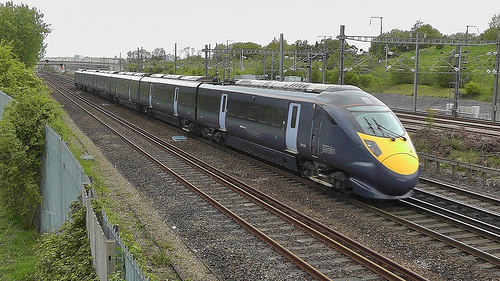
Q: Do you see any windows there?
A: Yes, there is a window.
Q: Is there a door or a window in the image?
A: Yes, there is a window.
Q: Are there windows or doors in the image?
A: Yes, there is a window.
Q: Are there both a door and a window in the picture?
A: Yes, there are both a window and a door.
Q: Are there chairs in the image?
A: No, there are no chairs.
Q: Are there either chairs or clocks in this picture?
A: No, there are no chairs or clocks.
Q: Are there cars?
A: No, there are no cars.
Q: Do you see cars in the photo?
A: No, there are no cars.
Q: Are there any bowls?
A: No, there are no bowls.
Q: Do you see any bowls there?
A: No, there are no bowls.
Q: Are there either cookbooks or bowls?
A: No, there are no bowls or cookbooks.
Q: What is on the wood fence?
A: The shrub is on the fence.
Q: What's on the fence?
A: The shrub is on the fence.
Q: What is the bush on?
A: The bush is on the fence.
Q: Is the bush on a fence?
A: Yes, the bush is on a fence.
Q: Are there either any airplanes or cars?
A: No, there are no cars or airplanes.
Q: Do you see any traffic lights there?
A: No, there are no traffic lights.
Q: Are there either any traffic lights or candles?
A: No, there are no traffic lights or candles.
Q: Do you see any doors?
A: Yes, there is a door.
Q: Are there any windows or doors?
A: Yes, there is a door.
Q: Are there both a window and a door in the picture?
A: Yes, there are both a door and a window.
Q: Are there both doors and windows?
A: Yes, there are both a door and a window.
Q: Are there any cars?
A: No, there are no cars.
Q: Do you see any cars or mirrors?
A: No, there are no cars or mirrors.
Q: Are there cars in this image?
A: No, there are no cars.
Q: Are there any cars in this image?
A: No, there are no cars.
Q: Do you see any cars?
A: No, there are no cars.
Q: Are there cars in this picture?
A: No, there are no cars.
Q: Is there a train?
A: Yes, there is a train.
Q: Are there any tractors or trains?
A: Yes, there is a train.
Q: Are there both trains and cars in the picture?
A: No, there is a train but no cars.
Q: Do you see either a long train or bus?
A: Yes, there is a long train.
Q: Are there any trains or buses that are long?
A: Yes, the train is long.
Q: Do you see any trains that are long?
A: Yes, there is a long train.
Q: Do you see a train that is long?
A: Yes, there is a train that is long.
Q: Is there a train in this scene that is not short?
A: Yes, there is a long train.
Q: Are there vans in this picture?
A: No, there are no vans.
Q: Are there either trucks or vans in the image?
A: No, there are no vans or trucks.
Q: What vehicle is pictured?
A: The vehicle is a train.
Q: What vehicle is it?
A: The vehicle is a train.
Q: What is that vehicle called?
A: This is a train.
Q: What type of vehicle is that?
A: This is a train.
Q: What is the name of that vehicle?
A: This is a train.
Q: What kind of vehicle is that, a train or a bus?
A: This is a train.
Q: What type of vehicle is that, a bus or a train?
A: This is a train.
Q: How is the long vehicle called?
A: The vehicle is a train.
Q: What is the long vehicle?
A: The vehicle is a train.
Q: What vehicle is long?
A: The vehicle is a train.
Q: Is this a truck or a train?
A: This is a train.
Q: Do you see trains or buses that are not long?
A: No, there is a train but it is long.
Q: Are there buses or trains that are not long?
A: No, there is a train but it is long.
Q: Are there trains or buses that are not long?
A: No, there is a train but it is long.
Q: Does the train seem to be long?
A: Yes, the train is long.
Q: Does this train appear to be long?
A: Yes, the train is long.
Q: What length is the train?
A: The train is long.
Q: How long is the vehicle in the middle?
A: The train is long.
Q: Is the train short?
A: No, the train is long.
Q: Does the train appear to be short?
A: No, the train is long.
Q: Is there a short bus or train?
A: No, there is a train but it is long.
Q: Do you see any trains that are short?
A: No, there is a train but it is long.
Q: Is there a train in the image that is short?
A: No, there is a train but it is long.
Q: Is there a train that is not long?
A: No, there is a train but it is long.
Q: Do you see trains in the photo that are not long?
A: No, there is a train but it is long.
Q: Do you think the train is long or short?
A: The train is long.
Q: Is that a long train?
A: Yes, that is a long train.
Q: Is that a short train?
A: No, that is a long train.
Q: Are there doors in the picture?
A: Yes, there is a door.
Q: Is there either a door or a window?
A: Yes, there is a door.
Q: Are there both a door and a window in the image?
A: Yes, there are both a door and a window.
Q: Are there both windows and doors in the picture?
A: Yes, there are both a door and a window.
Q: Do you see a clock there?
A: No, there are no clocks.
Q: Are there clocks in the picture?
A: No, there are no clocks.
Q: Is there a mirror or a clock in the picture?
A: No, there are no clocks or mirrors.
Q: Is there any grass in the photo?
A: Yes, there is grass.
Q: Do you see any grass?
A: Yes, there is grass.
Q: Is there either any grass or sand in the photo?
A: Yes, there is grass.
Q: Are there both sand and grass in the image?
A: No, there is grass but no sand.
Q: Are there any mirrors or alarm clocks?
A: No, there are no mirrors or alarm clocks.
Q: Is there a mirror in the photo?
A: No, there are no mirrors.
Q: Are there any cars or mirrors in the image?
A: No, there are no mirrors or cars.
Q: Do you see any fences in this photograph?
A: Yes, there is a fence.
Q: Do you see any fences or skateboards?
A: Yes, there is a fence.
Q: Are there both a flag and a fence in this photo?
A: No, there is a fence but no flags.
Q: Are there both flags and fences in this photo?
A: No, there is a fence but no flags.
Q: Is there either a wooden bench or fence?
A: Yes, there is a wood fence.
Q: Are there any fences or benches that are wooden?
A: Yes, the fence is wooden.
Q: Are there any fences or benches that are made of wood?
A: Yes, the fence is made of wood.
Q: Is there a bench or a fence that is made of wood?
A: Yes, the fence is made of wood.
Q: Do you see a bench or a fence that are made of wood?
A: Yes, the fence is made of wood.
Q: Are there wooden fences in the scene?
A: Yes, there is a wood fence.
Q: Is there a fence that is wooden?
A: Yes, there is a fence that is wooden.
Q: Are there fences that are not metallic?
A: Yes, there is a wooden fence.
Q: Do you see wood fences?
A: Yes, there is a fence that is made of wood.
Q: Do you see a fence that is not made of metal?
A: Yes, there is a fence that is made of wood.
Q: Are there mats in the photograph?
A: No, there are no mats.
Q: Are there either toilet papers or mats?
A: No, there are no mats or toilet papers.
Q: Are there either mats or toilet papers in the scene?
A: No, there are no mats or toilet papers.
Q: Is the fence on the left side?
A: Yes, the fence is on the left of the image.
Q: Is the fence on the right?
A: No, the fence is on the left of the image.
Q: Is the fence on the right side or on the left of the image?
A: The fence is on the left of the image.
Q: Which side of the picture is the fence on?
A: The fence is on the left of the image.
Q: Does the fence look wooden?
A: Yes, the fence is wooden.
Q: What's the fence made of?
A: The fence is made of wood.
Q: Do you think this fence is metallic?
A: No, the fence is wooden.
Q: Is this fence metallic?
A: No, the fence is wooden.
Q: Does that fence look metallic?
A: No, the fence is wooden.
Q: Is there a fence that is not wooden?
A: No, there is a fence but it is wooden.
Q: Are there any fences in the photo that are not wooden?
A: No, there is a fence but it is wooden.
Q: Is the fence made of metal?
A: No, the fence is made of wood.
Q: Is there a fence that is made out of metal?
A: No, there is a fence but it is made of wood.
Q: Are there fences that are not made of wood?
A: No, there is a fence but it is made of wood.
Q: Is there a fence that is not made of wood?
A: No, there is a fence but it is made of wood.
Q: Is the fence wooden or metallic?
A: The fence is wooden.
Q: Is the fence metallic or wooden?
A: The fence is wooden.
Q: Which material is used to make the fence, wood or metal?
A: The fence is made of wood.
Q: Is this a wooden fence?
A: Yes, this is a wooden fence.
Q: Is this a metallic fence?
A: No, this is a wooden fence.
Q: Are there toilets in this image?
A: No, there are no toilets.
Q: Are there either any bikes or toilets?
A: No, there are no toilets or bikes.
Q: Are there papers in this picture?
A: No, there are no papers.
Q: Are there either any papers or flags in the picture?
A: No, there are no papers or flags.